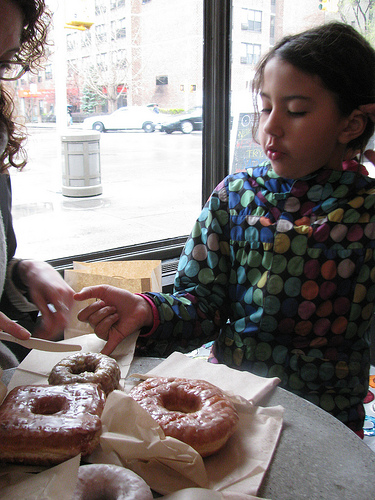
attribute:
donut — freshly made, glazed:
[50, 352, 122, 393]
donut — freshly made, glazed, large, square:
[1, 381, 105, 465]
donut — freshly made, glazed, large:
[128, 376, 239, 458]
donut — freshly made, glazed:
[75, 463, 153, 499]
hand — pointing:
[72, 281, 151, 357]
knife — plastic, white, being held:
[1, 331, 82, 353]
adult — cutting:
[1, 1, 75, 368]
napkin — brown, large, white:
[136, 351, 281, 408]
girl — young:
[74, 22, 375, 441]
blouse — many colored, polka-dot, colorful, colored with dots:
[136, 162, 375, 441]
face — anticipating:
[260, 55, 319, 179]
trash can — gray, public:
[59, 133, 104, 199]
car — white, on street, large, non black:
[84, 104, 166, 134]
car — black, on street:
[161, 111, 202, 136]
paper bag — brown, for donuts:
[63, 259, 164, 340]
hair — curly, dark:
[1, 1, 53, 176]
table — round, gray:
[1, 355, 375, 500]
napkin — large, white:
[6, 327, 139, 400]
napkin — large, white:
[101, 389, 285, 495]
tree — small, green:
[79, 83, 102, 116]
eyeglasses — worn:
[1, 53, 31, 85]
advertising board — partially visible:
[231, 110, 269, 173]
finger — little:
[99, 335, 120, 356]